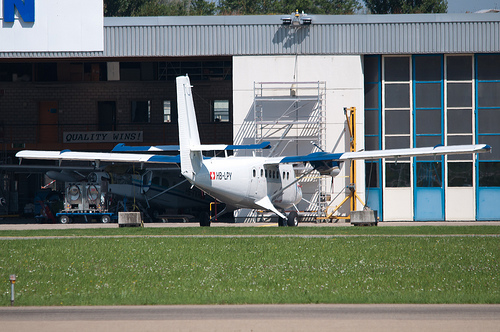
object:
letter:
[225, 172, 233, 182]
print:
[208, 172, 217, 181]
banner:
[62, 130, 146, 144]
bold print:
[61, 129, 145, 142]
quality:
[63, 132, 109, 141]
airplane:
[12, 73, 490, 229]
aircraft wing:
[278, 142, 492, 170]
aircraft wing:
[13, 147, 180, 173]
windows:
[382, 107, 409, 137]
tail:
[173, 71, 205, 172]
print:
[110, 132, 143, 142]